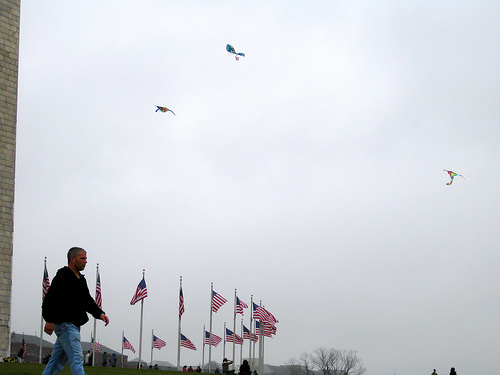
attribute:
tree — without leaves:
[289, 348, 371, 373]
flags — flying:
[208, 281, 228, 320]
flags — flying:
[128, 269, 154, 305]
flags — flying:
[227, 279, 252, 319]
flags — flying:
[253, 288, 283, 348]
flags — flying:
[86, 259, 108, 316]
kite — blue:
[223, 42, 245, 62]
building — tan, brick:
[0, 2, 17, 364]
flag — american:
[39, 257, 52, 301]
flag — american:
[211, 286, 224, 311]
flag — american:
[123, 274, 149, 306]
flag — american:
[246, 299, 281, 337]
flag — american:
[122, 332, 141, 358]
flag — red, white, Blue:
[130, 277, 149, 304]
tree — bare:
[306, 347, 341, 373]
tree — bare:
[324, 345, 361, 374]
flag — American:
[249, 302, 272, 324]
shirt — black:
[44, 265, 103, 332]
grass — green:
[1, 345, 226, 374]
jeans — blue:
[46, 324, 86, 373]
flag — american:
[204, 286, 298, 364]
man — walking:
[39, 245, 109, 372]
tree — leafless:
[288, 342, 355, 373]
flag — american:
[114, 245, 155, 372]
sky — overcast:
[136, 1, 473, 293]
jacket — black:
[44, 236, 121, 371]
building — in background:
[78, 338, 129, 372]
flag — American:
[198, 283, 233, 315]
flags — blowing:
[202, 286, 279, 347]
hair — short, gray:
[56, 233, 101, 284]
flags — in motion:
[91, 263, 285, 361]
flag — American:
[29, 261, 78, 374]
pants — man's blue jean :
[41, 325, 81, 374]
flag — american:
[127, 268, 148, 368]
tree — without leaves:
[287, 348, 364, 373]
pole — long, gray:
[125, 257, 165, 372]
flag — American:
[63, 296, 261, 375]